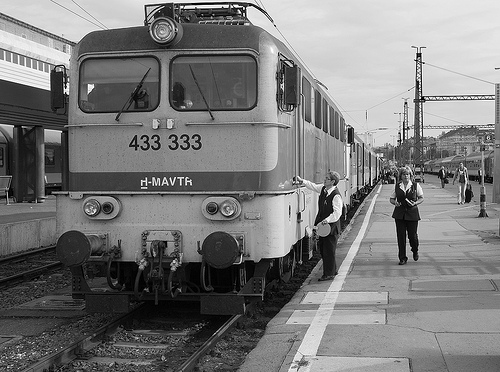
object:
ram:
[194, 230, 244, 268]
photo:
[0, 1, 500, 370]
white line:
[286, 183, 388, 369]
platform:
[238, 175, 499, 372]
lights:
[216, 200, 243, 220]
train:
[50, 0, 386, 315]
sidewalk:
[237, 180, 500, 371]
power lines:
[366, 86, 415, 113]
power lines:
[421, 62, 500, 88]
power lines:
[419, 110, 474, 126]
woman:
[292, 170, 348, 283]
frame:
[410, 44, 499, 169]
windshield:
[109, 65, 153, 127]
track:
[19, 304, 243, 371]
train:
[47, 0, 394, 320]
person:
[453, 159, 471, 206]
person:
[436, 165, 452, 188]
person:
[390, 166, 425, 269]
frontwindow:
[168, 51, 258, 111]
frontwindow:
[76, 53, 161, 113]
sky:
[0, 0, 500, 149]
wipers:
[179, 60, 219, 121]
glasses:
[324, 175, 331, 182]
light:
[148, 17, 182, 44]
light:
[79, 198, 100, 218]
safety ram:
[54, 228, 96, 268]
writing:
[139, 174, 194, 193]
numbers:
[191, 133, 203, 151]